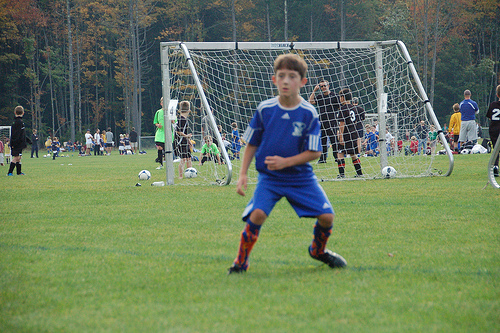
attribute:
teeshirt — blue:
[235, 94, 318, 178]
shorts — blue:
[240, 176, 333, 223]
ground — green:
[119, 172, 213, 227]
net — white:
[170, 55, 236, 127]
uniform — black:
[7, 118, 29, 156]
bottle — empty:
[146, 175, 165, 191]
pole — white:
[403, 46, 452, 177]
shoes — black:
[216, 253, 358, 291]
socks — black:
[5, 156, 23, 181]